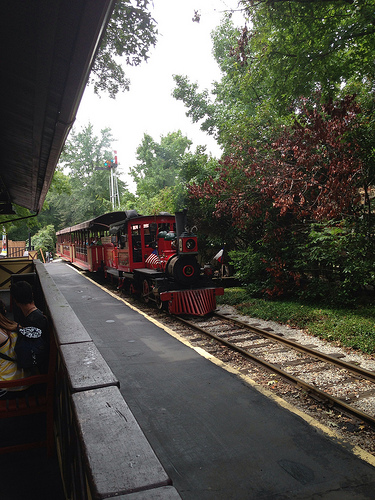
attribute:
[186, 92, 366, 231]
leaves — brown, red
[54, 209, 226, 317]
train — red, black, large, old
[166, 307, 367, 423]
tracks — metal, brown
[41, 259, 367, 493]
pavement — black, sidewalk, walkway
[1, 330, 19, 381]
shirt — white, yellow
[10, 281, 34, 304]
hair — black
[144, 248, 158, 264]
flag — red, blue, white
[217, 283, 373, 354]
grass — green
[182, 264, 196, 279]
circle — red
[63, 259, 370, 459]
line — yellow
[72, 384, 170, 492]
stone — grey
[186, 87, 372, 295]
tree — red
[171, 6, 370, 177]
tree — large, green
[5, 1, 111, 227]
hang — roof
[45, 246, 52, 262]
person — standing, waiting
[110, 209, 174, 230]
roof — black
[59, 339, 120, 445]
block — concrete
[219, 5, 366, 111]
leaves — green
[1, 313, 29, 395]
person — sitting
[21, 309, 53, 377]
shirt — black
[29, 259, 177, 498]
wall — stone